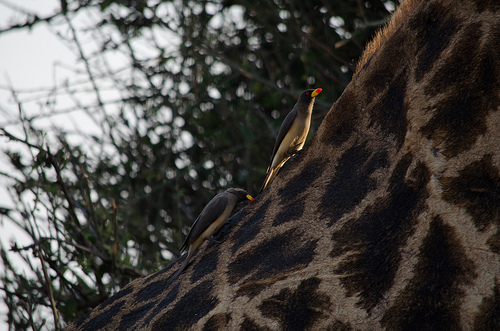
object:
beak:
[246, 194, 256, 202]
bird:
[257, 88, 322, 198]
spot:
[441, 151, 500, 229]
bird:
[167, 187, 255, 283]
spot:
[152, 280, 221, 331]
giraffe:
[63, 0, 500, 331]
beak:
[310, 88, 322, 97]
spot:
[234, 312, 268, 331]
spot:
[313, 139, 387, 230]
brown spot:
[252, 277, 331, 331]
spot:
[465, 276, 500, 331]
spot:
[434, 147, 500, 235]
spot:
[254, 271, 333, 331]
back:
[64, 0, 499, 331]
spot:
[378, 213, 476, 331]